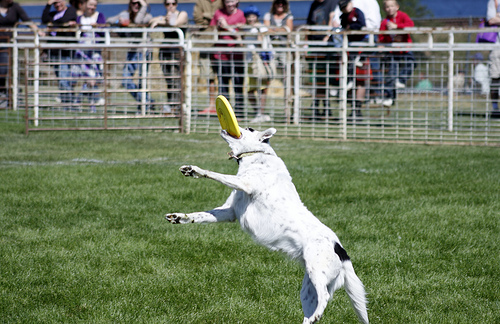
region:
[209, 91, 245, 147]
The yellow frisbee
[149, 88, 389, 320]
a dog with a frisbee in its mouth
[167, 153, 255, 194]
the dog's front left leg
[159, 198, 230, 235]
the dog's front right leg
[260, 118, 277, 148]
the dog's left ear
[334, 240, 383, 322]
the black and white tail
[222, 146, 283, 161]
the dog's collar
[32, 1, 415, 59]
spectators in the distance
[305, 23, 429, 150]
a metal fence in the distance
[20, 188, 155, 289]
bright green grass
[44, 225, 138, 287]
the grass is green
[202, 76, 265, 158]
the Frisbee is green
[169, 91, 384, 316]
the dog is white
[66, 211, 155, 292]
the grass is short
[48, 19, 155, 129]
the fence is white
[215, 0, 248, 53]
the shirt is pink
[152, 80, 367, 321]
the dog is jumping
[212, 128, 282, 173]
the dog has a collar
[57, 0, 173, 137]
the people are standing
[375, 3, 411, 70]
the shirt is red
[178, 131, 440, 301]
the dog is white and black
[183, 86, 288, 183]
the dog has a frisbee in his mouth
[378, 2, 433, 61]
the child has on a red shirt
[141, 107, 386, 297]
the dog is jumping up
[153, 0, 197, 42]
the woman has on sunglasses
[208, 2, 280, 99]
the woman is wearing a pink shirt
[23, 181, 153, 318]
the grass is very green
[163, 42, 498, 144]
the people stand behind a metal fence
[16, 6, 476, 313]
it is a sunny day out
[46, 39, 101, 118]
the person has on jeans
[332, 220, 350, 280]
this is a spot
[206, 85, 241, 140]
this is a frisbee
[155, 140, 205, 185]
the front left paw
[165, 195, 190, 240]
the front right paw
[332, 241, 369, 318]
This is a dog tail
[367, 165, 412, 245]
This is green grass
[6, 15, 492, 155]
This is a fence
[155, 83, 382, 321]
This is a dog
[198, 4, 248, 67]
this is a pink shirt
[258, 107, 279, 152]
this is a dog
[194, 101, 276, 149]
dog catching a yellow frisbee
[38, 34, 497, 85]
fence around the grass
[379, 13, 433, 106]
child standing on the fence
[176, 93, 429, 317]
dog leaping to catch frisbee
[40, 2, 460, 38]
people watching the dog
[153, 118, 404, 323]
black and white dog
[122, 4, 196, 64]
women wearing sunglasses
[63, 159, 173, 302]
bright green grass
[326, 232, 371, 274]
black spot on the dog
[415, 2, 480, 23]
blue roof on the building